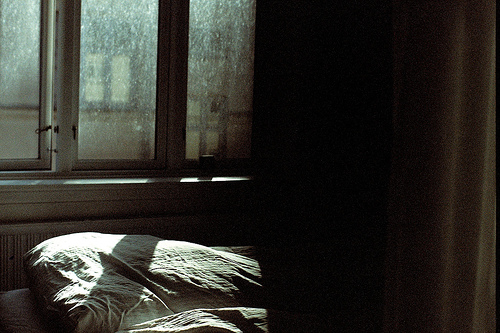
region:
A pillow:
[84, 247, 145, 318]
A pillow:
[131, 247, 206, 325]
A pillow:
[45, 185, 186, 290]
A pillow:
[81, 202, 198, 327]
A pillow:
[137, 240, 257, 323]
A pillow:
[166, 305, 216, 325]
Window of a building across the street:
[80, 47, 145, 117]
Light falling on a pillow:
[36, 234, 102, 289]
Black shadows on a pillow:
[98, 231, 155, 311]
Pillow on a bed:
[13, 233, 271, 313]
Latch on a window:
[33, 122, 54, 134]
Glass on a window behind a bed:
[191, 3, 254, 168]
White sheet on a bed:
[3, 291, 56, 331]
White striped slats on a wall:
[1, 221, 286, 280]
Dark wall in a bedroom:
[391, 20, 498, 328]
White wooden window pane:
[39, 1, 54, 166]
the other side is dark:
[263, 85, 401, 259]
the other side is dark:
[299, 97, 366, 182]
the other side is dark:
[253, 15, 370, 183]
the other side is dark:
[292, 167, 350, 234]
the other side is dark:
[260, 48, 465, 302]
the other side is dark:
[319, 84, 381, 175]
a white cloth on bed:
[53, 227, 275, 328]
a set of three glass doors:
[19, 10, 264, 165]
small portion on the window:
[33, 118, 63, 177]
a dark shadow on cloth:
[110, 218, 170, 328]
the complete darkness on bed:
[261, 12, 468, 331]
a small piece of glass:
[84, 8, 159, 172]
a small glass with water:
[181, 3, 255, 158]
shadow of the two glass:
[81, 41, 161, 108]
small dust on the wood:
[68, 125, 88, 143]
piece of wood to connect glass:
[36, 1, 91, 174]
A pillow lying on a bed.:
[20, 231, 272, 332]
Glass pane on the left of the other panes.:
[0, 0, 47, 172]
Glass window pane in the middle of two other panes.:
[76, 0, 157, 160]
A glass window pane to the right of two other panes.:
[185, 0, 257, 167]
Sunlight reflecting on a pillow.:
[28, 227, 110, 304]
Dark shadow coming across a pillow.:
[70, 229, 162, 331]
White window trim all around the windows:
[3, 1, 189, 206]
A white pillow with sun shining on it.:
[18, 231, 264, 329]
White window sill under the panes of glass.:
[0, 169, 260, 187]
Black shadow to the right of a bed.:
[255, 1, 406, 331]